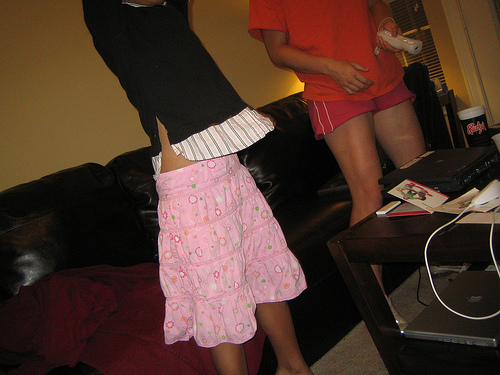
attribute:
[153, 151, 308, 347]
skirt — pink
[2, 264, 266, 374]
fabric — red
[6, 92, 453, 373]
couch — black, leather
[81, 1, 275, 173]
top — black, white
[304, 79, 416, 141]
shorts — red, short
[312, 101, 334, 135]
stripes — white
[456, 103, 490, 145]
cup — platic, black, plastic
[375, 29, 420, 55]
controller — for the wii, white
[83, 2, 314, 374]
girl — standing up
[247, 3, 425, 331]
girl — standing up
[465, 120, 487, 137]
writing — red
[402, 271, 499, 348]
laptop — silver, apple, closed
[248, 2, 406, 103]
shirt — orange